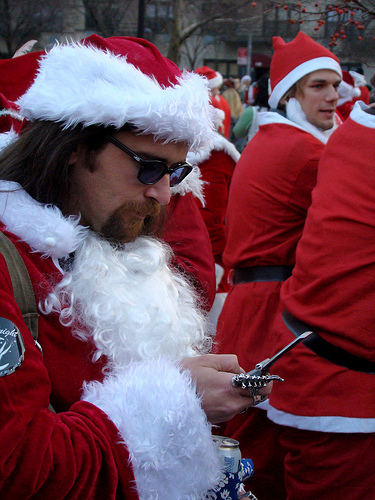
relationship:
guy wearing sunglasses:
[0, 34, 272, 500] [108, 125, 190, 186]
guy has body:
[0, 34, 272, 500] [10, 235, 179, 498]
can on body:
[204, 433, 243, 483] [10, 235, 179, 498]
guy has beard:
[208, 30, 342, 374] [286, 95, 328, 142]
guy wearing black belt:
[208, 30, 342, 374] [222, 260, 289, 283]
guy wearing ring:
[0, 34, 272, 500] [228, 373, 286, 390]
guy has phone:
[0, 34, 272, 500] [230, 328, 313, 387]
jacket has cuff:
[1, 185, 225, 497] [197, 129, 242, 163]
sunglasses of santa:
[108, 126, 215, 199] [2, 33, 269, 428]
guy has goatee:
[0, 34, 272, 500] [101, 200, 173, 248]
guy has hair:
[0, 34, 272, 500] [2, 113, 110, 186]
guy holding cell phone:
[0, 34, 272, 500] [224, 306, 326, 415]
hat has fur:
[0, 32, 219, 161] [15, 38, 214, 155]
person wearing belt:
[265, 99, 372, 498] [280, 304, 373, 374]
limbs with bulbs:
[320, 5, 355, 30] [228, 355, 279, 391]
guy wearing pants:
[0, 34, 272, 500] [257, 399, 374, 491]